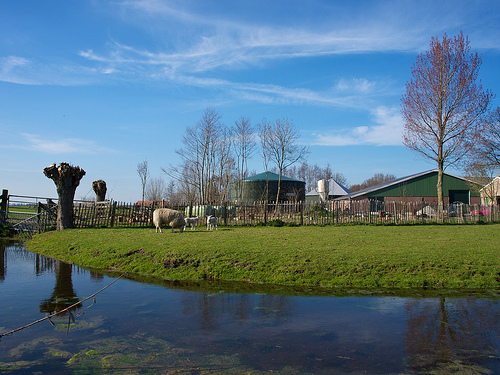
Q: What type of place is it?
A: It is a pond.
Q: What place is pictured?
A: It is a pond.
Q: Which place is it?
A: It is a pond.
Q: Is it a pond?
A: Yes, it is a pond.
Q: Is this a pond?
A: Yes, it is a pond.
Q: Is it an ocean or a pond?
A: It is a pond.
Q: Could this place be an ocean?
A: No, it is a pond.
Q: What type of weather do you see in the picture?
A: It is cloudy.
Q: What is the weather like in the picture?
A: It is cloudy.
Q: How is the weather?
A: It is cloudy.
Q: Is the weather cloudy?
A: Yes, it is cloudy.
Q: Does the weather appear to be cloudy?
A: Yes, it is cloudy.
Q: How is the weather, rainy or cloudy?
A: It is cloudy.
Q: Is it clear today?
A: No, it is cloudy.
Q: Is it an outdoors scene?
A: Yes, it is outdoors.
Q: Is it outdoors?
A: Yes, it is outdoors.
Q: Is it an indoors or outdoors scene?
A: It is outdoors.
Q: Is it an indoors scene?
A: No, it is outdoors.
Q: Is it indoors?
A: No, it is outdoors.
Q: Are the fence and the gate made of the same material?
A: No, the fence is made of wood and the gate is made of metal.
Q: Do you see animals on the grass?
A: Yes, there are animals on the grass.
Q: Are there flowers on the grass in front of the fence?
A: No, there are animals on the grass.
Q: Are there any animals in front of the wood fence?
A: Yes, there are animals in front of the fence.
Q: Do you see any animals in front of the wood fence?
A: Yes, there are animals in front of the fence.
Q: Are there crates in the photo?
A: No, there are no crates.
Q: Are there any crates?
A: No, there are no crates.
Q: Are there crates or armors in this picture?
A: No, there are no crates or armors.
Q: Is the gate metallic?
A: Yes, the gate is metallic.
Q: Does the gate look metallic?
A: Yes, the gate is metallic.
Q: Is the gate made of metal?
A: Yes, the gate is made of metal.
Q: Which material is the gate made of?
A: The gate is made of metal.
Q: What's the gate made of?
A: The gate is made of metal.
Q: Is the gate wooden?
A: No, the gate is metallic.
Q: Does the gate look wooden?
A: No, the gate is metallic.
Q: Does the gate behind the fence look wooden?
A: No, the gate is metallic.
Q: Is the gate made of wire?
A: No, the gate is made of metal.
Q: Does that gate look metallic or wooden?
A: The gate is metallic.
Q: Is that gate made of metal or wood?
A: The gate is made of metal.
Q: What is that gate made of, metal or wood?
A: The gate is made of metal.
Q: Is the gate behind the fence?
A: Yes, the gate is behind the fence.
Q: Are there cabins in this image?
A: No, there are no cabins.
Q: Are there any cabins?
A: No, there are no cabins.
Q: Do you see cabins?
A: No, there are no cabins.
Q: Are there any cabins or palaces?
A: No, there are no cabins or palaces.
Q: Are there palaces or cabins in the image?
A: No, there are no cabins or palaces.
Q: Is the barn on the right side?
A: Yes, the barn is on the right of the image.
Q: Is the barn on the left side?
A: No, the barn is on the right of the image.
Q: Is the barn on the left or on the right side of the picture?
A: The barn is on the right of the image.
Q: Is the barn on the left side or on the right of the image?
A: The barn is on the right of the image.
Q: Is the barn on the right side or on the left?
A: The barn is on the right of the image.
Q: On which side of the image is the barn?
A: The barn is on the right of the image.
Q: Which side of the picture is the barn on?
A: The barn is on the right of the image.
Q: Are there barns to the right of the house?
A: Yes, there is a barn to the right of the house.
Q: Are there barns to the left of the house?
A: No, the barn is to the right of the house.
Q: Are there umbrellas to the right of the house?
A: No, there is a barn to the right of the house.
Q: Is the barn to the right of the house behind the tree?
A: Yes, the barn is to the right of the house.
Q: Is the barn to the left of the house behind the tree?
A: No, the barn is to the right of the house.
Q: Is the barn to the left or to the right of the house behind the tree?
A: The barn is to the right of the house.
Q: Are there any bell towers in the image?
A: No, there are no bell towers.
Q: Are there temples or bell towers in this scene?
A: No, there are no bell towers or temples.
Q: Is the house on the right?
A: Yes, the house is on the right of the image.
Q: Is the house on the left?
A: No, the house is on the right of the image.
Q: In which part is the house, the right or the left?
A: The house is on the right of the image.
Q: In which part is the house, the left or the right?
A: The house is on the right of the image.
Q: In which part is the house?
A: The house is on the right of the image.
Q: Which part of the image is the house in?
A: The house is on the right of the image.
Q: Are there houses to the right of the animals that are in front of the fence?
A: Yes, there is a house to the right of the animals.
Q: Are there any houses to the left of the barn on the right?
A: Yes, there is a house to the left of the barn.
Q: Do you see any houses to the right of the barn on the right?
A: No, the house is to the left of the barn.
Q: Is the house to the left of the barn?
A: Yes, the house is to the left of the barn.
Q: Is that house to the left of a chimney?
A: No, the house is to the left of the barn.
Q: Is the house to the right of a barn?
A: No, the house is to the left of a barn.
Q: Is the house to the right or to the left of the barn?
A: The house is to the left of the barn.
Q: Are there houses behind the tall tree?
A: Yes, there is a house behind the tree.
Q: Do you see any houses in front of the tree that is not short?
A: No, the house is behind the tree.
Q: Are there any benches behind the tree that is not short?
A: No, there is a house behind the tree.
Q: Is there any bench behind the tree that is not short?
A: No, there is a house behind the tree.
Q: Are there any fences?
A: Yes, there is a fence.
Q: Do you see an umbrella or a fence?
A: Yes, there is a fence.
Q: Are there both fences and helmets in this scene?
A: No, there is a fence but no helmets.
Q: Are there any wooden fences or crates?
A: Yes, there is a wood fence.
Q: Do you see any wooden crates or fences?
A: Yes, there is a wood fence.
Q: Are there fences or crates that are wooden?
A: Yes, the fence is wooden.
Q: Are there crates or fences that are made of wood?
A: Yes, the fence is made of wood.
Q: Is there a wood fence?
A: Yes, there is a fence that is made of wood.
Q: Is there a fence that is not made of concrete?
A: Yes, there is a fence that is made of wood.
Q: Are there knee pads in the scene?
A: No, there are no knee pads.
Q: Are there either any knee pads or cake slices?
A: No, there are no knee pads or cake slices.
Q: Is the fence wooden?
A: Yes, the fence is wooden.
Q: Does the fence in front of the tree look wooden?
A: Yes, the fence is wooden.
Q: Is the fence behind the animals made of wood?
A: Yes, the fence is made of wood.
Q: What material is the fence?
A: The fence is made of wood.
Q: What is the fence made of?
A: The fence is made of wood.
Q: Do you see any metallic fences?
A: No, there is a fence but it is wooden.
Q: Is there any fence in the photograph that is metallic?
A: No, there is a fence but it is wooden.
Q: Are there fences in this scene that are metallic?
A: No, there is a fence but it is wooden.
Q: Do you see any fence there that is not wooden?
A: No, there is a fence but it is wooden.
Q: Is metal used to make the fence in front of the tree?
A: No, the fence is made of wood.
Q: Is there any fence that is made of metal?
A: No, there is a fence but it is made of wood.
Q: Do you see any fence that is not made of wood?
A: No, there is a fence but it is made of wood.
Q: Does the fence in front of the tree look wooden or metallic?
A: The fence is wooden.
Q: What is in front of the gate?
A: The fence is in front of the gate.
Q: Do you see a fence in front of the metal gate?
A: Yes, there is a fence in front of the gate.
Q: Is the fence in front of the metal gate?
A: Yes, the fence is in front of the gate.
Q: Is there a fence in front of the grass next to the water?
A: No, the fence is behind the grass.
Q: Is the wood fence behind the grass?
A: Yes, the fence is behind the grass.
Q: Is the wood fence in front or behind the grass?
A: The fence is behind the grass.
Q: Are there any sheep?
A: Yes, there is a sheep.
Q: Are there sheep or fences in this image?
A: Yes, there is a sheep.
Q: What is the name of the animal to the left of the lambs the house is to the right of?
A: The animal is a sheep.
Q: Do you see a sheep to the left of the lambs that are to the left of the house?
A: Yes, there is a sheep to the left of the lambs.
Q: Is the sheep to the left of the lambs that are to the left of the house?
A: Yes, the sheep is to the left of the lambs.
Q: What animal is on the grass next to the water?
A: The animal is a sheep.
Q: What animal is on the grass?
A: The animal is a sheep.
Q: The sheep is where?
A: The sheep is on the grass.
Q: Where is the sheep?
A: The sheep is on the grass.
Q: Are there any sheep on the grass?
A: Yes, there is a sheep on the grass.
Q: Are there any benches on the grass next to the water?
A: No, there is a sheep on the grass.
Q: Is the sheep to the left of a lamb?
A: Yes, the sheep is to the left of a lamb.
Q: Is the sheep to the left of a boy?
A: No, the sheep is to the left of a lamb.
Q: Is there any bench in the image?
A: No, there are no benches.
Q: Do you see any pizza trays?
A: No, there are no pizza trays.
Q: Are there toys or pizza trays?
A: No, there are no pizza trays or toys.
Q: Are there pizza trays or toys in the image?
A: No, there are no pizza trays or toys.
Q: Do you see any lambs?
A: Yes, there are lambs.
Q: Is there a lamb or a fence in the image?
A: Yes, there are lambs.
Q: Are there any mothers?
A: No, there are no mothers.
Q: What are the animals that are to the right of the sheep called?
A: The animals are lambs.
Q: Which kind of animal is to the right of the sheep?
A: The animals are lambs.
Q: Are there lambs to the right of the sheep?
A: Yes, there are lambs to the right of the sheep.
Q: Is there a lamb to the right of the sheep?
A: Yes, there are lambs to the right of the sheep.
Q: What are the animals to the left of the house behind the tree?
A: The animals are lambs.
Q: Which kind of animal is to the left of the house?
A: The animals are lambs.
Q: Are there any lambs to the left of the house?
A: Yes, there are lambs to the left of the house.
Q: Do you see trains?
A: No, there are no trains.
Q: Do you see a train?
A: No, there are no trains.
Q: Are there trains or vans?
A: No, there are no trains or vans.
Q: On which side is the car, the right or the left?
A: The car is on the right of the image.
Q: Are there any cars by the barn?
A: Yes, there is a car by the barn.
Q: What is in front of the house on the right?
A: The tree is in front of the house.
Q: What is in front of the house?
A: The tree is in front of the house.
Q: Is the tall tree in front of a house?
A: Yes, the tree is in front of a house.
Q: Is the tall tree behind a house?
A: No, the tree is in front of a house.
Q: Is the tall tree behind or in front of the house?
A: The tree is in front of the house.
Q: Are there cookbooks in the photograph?
A: No, there are no cookbooks.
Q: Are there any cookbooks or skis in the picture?
A: No, there are no cookbooks or skis.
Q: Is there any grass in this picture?
A: Yes, there is grass.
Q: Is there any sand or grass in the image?
A: Yes, there is grass.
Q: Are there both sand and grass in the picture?
A: No, there is grass but no sand.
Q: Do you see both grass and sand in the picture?
A: No, there is grass but no sand.